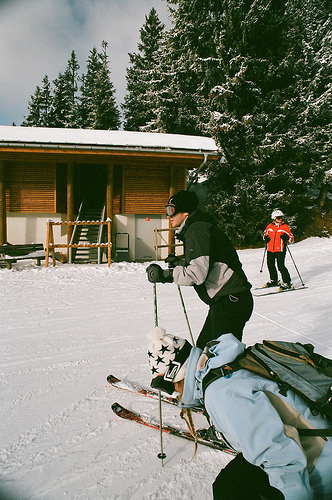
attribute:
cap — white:
[138, 319, 199, 396]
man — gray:
[146, 186, 252, 352]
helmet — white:
[262, 199, 283, 224]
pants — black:
[192, 289, 254, 341]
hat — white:
[148, 324, 189, 382]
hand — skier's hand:
[253, 228, 272, 246]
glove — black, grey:
[145, 262, 174, 281]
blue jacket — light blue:
[227, 51, 252, 82]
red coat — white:
[262, 221, 294, 253]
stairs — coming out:
[62, 169, 112, 270]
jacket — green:
[171, 209, 252, 306]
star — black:
[158, 344, 171, 354]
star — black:
[153, 354, 163, 365]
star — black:
[170, 334, 179, 344]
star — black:
[149, 365, 158, 377]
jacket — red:
[261, 218, 294, 251]